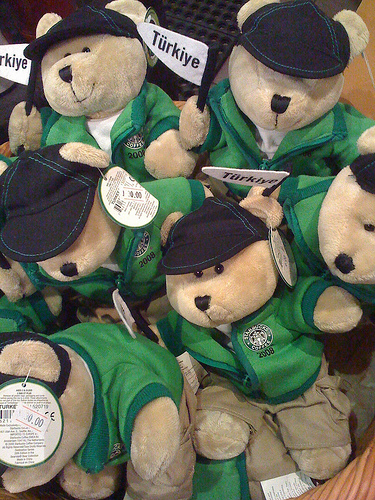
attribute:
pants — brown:
[195, 366, 353, 449]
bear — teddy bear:
[149, 207, 369, 485]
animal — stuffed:
[155, 191, 365, 482]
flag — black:
[144, 24, 214, 82]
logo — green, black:
[243, 319, 273, 349]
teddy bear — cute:
[157, 193, 364, 480]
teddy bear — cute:
[181, 1, 372, 177]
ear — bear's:
[240, 195, 283, 228]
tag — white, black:
[133, 17, 212, 86]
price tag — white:
[12, 403, 51, 434]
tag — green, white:
[87, 145, 155, 220]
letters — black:
[147, 23, 205, 83]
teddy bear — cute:
[25, 0, 188, 177]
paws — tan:
[175, 92, 211, 149]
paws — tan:
[139, 136, 197, 176]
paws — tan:
[7, 92, 43, 152]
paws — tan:
[313, 286, 364, 334]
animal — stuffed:
[202, 5, 372, 172]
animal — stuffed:
[29, 8, 183, 175]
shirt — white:
[137, 137, 321, 280]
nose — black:
[268, 91, 294, 124]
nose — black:
[53, 60, 81, 89]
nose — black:
[329, 251, 360, 277]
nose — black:
[58, 260, 82, 278]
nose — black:
[188, 292, 213, 310]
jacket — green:
[176, 287, 330, 406]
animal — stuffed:
[142, 205, 347, 456]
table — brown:
[339, 0, 373, 124]